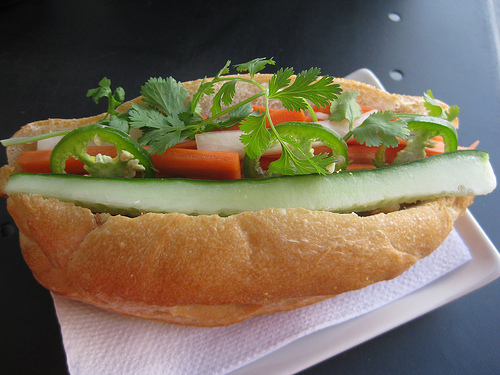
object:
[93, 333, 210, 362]
napkin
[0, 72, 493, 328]
sandwhich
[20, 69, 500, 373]
plate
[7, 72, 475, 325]
bread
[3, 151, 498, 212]
pickle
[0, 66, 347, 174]
cilantro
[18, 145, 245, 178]
carrots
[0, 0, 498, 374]
table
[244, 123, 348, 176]
jalepeno peppers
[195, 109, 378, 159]
onion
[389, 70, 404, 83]
holes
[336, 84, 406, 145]
vegetables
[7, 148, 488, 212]
peel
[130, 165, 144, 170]
seeds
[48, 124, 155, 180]
jalepeno pepper